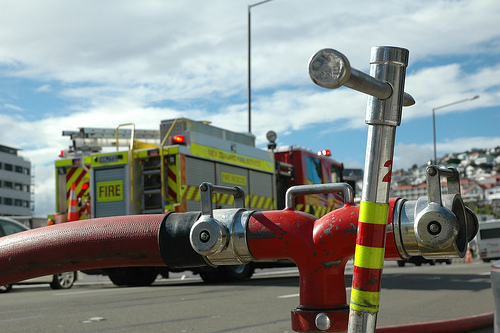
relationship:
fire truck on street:
[54, 117, 355, 295] [4, 254, 499, 331]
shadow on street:
[259, 270, 490, 291] [4, 254, 499, 331]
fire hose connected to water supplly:
[2, 209, 169, 290] [245, 195, 398, 330]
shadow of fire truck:
[259, 270, 490, 291] [54, 117, 355, 295]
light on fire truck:
[323, 149, 332, 158] [54, 117, 355, 295]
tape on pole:
[345, 202, 392, 314] [430, 93, 482, 198]